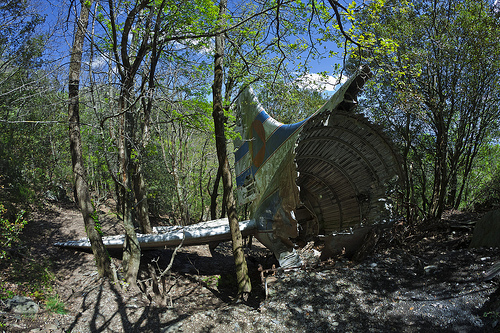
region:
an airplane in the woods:
[76, 34, 474, 330]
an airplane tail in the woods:
[62, 34, 489, 331]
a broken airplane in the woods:
[32, 34, 490, 286]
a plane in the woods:
[71, 8, 475, 332]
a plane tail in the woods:
[69, 57, 495, 312]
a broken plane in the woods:
[41, 22, 471, 329]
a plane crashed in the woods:
[53, 34, 499, 314]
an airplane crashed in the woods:
[46, 46, 493, 314]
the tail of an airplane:
[12, 41, 422, 331]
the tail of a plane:
[76, 38, 488, 304]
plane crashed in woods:
[231, 72, 462, 297]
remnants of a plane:
[221, 52, 449, 299]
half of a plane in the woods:
[225, 62, 421, 267]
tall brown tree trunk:
[210, 2, 264, 303]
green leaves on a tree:
[345, 1, 496, 96]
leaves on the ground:
[1, 270, 96, 331]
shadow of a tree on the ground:
[49, 278, 246, 332]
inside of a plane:
[300, 107, 405, 257]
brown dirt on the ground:
[55, 284, 182, 331]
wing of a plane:
[50, 215, 252, 266]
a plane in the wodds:
[66, 6, 498, 308]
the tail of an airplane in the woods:
[28, 12, 497, 298]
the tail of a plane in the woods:
[83, 28, 410, 324]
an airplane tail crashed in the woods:
[73, 43, 424, 327]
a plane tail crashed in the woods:
[87, 61, 414, 331]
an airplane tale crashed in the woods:
[117, 31, 464, 327]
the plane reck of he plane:
[73, 40, 436, 305]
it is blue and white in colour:
[54, 13, 415, 296]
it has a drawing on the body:
[198, 104, 275, 169]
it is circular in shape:
[266, 130, 406, 251]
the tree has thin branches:
[407, 27, 499, 202]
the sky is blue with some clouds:
[71, 18, 353, 81]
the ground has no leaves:
[101, 275, 498, 332]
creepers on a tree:
[73, 197, 114, 329]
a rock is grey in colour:
[8, 264, 45, 331]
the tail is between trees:
[124, 15, 439, 331]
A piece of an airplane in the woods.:
[215, 94, 409, 243]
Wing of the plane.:
[59, 211, 230, 258]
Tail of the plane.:
[213, 57, 296, 150]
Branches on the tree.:
[30, 63, 175, 129]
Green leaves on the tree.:
[352, 18, 413, 78]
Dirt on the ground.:
[193, 280, 384, 325]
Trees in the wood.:
[18, 28, 410, 133]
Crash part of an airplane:
[121, 101, 431, 242]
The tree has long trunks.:
[54, 26, 146, 330]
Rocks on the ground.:
[301, 267, 471, 305]